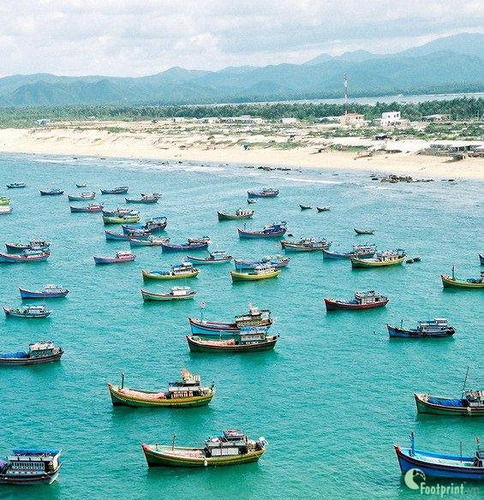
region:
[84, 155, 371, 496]
Boats on the water.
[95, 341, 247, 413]
Boat on the water.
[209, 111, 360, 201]
Beach against the water.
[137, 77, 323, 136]
Trees in the background.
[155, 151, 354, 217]
Water along the beach.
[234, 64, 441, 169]
Buildings on the beach.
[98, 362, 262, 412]
Yellow boat in the water.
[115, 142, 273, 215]
Waves on the shore.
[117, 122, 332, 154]
Grass on the beach.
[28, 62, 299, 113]
Mountains in the background.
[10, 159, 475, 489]
lots of fishing boats in the ocean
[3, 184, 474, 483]
boats are in shallow water near the shore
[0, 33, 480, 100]
mountains behind the shore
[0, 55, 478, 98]
trees and foilage on the mountains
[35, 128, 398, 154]
seaweed on the shore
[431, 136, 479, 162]
a small building on the beach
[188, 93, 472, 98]
another body of water on the other side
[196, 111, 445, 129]
buildings along the back of the beach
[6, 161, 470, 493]
ripples in the water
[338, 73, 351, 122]
tall pole used as a shore marker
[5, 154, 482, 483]
A large group of boats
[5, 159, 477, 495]
Blue green sea near the shore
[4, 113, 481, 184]
White sand beach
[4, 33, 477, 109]
Mountains in the background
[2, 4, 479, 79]
A cloudy sky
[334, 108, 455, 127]
Three low buildings on the beach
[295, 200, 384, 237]
Three small boats near the shore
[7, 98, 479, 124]
A line of trees behind the beach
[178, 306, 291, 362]
Two boats anchored close together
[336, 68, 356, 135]
A red and white signal tower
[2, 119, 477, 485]
beach area with sand and water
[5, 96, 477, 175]
sand on the beach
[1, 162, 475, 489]
water with boats in it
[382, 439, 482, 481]
blue boat in the water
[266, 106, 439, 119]
buildings on the sand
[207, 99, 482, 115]
trees on the beach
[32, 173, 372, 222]
boats near the sand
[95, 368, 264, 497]
boats furthest away from sand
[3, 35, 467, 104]
elevated terrain in distance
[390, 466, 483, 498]
credit for the image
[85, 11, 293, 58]
this is the sky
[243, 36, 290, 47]
the sky is blue in color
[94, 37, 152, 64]
these are the clouds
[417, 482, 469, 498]
this is a writing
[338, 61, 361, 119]
this is a satellite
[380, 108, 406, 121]
this is a building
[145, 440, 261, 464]
this is a boat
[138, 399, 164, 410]
the boat is brown in color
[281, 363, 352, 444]
this is a water body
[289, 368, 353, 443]
the water is calm